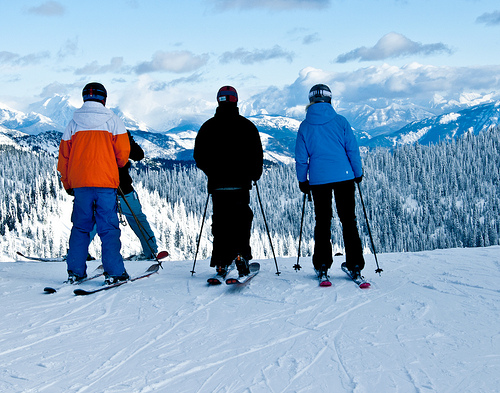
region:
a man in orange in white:
[54, 78, 131, 285]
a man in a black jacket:
[192, 84, 264, 285]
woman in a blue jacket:
[293, 83, 365, 275]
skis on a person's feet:
[207, 261, 260, 284]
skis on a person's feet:
[312, 262, 371, 289]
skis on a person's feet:
[43, 260, 163, 295]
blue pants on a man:
[64, 187, 126, 284]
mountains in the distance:
[2, 99, 499, 161]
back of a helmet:
[216, 84, 236, 104]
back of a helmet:
[78, 84, 106, 103]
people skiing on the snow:
[67, 18, 465, 350]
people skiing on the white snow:
[21, 34, 498, 383]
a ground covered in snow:
[47, 261, 464, 382]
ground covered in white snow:
[148, 283, 344, 390]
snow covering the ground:
[97, 248, 362, 383]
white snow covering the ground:
[89, 258, 368, 390]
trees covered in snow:
[315, 130, 495, 233]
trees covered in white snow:
[368, 143, 499, 233]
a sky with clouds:
[126, 22, 461, 139]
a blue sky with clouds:
[126, 29, 433, 130]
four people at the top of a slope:
[42, 69, 412, 297]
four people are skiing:
[47, 68, 390, 304]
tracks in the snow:
[37, 307, 369, 392]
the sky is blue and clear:
[7, 3, 495, 45]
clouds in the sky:
[60, 26, 456, 91]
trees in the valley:
[12, 130, 498, 242]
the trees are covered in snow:
[0, 146, 497, 247]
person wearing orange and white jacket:
[52, 100, 150, 201]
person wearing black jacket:
[182, 99, 276, 194]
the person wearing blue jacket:
[276, 106, 395, 196]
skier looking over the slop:
[292, 82, 384, 288]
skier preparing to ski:
[44, 82, 163, 298]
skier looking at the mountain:
[186, 84, 283, 286]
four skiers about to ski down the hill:
[56, 80, 382, 291]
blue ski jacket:
[295, 102, 365, 192]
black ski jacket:
[190, 107, 263, 192]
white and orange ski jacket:
[57, 100, 130, 191]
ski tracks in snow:
[109, 292, 394, 390]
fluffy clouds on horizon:
[333, 31, 491, 101]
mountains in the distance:
[353, 88, 499, 140]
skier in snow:
[48, 71, 175, 312]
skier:
[178, 71, 278, 306]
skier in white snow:
[292, 73, 394, 300]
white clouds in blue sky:
[17, 6, 69, 48]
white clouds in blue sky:
[60, 25, 115, 56]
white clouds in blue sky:
[118, 29, 179, 79]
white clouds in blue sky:
[202, 16, 282, 64]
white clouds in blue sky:
[297, 29, 354, 60]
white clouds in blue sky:
[364, 23, 421, 70]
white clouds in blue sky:
[388, 22, 460, 63]